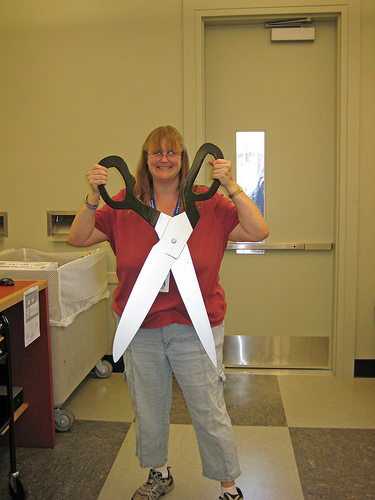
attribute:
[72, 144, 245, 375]
shears — novelty, large, big, giant, silver, black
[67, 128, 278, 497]
woman — white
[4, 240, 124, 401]
bin — large, white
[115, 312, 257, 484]
pants — gray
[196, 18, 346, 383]
door — white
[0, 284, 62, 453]
desk — wooden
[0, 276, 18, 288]
mouse — black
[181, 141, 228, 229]
handles — black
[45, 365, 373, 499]
floor — black, white, checkerboard pattern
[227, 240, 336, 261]
bar — silver, metal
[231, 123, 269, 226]
window — small, smalll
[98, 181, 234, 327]
shirt — red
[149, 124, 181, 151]
hair — brown